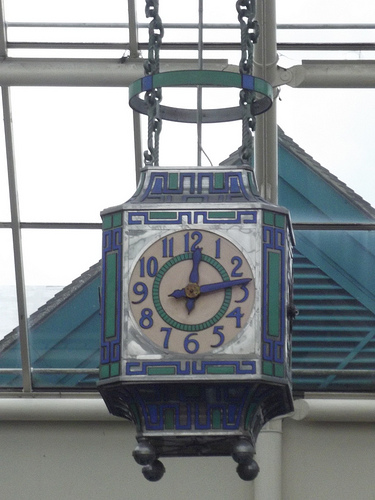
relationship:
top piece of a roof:
[217, 125, 317, 167] [1, 125, 374, 389]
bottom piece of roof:
[2, 373, 374, 394] [1, 125, 374, 389]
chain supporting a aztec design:
[236, 0, 262, 166] [95, 167, 296, 482]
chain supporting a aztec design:
[145, 1, 165, 165] [95, 167, 296, 482]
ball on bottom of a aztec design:
[229, 440, 256, 464] [95, 167, 296, 482]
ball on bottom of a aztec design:
[235, 460, 260, 482] [95, 167, 296, 482]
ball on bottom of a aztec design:
[140, 461, 166, 482] [95, 167, 296, 482]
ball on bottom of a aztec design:
[130, 443, 156, 468] [95, 167, 296, 482]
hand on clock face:
[169, 278, 252, 301] [122, 211, 262, 382]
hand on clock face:
[186, 245, 203, 316] [122, 211, 262, 382]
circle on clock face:
[154, 252, 233, 332] [122, 211, 262, 382]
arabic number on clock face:
[183, 232, 205, 255] [122, 211, 262, 382]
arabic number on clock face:
[160, 238, 175, 260] [122, 211, 262, 382]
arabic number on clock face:
[229, 256, 247, 279] [122, 211, 262, 382]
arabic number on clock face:
[129, 282, 150, 307] [122, 211, 262, 382]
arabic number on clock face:
[139, 307, 155, 330] [122, 211, 262, 382]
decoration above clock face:
[140, 171, 255, 204] [122, 211, 262, 382]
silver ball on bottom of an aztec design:
[229, 440, 256, 464] [95, 167, 296, 482]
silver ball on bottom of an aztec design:
[235, 460, 260, 482] [95, 167, 296, 482]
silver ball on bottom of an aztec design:
[130, 443, 156, 468] [95, 167, 296, 482]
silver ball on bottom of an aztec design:
[140, 461, 166, 482] [95, 167, 296, 482]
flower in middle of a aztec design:
[183, 282, 200, 300] [95, 167, 296, 482]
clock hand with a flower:
[186, 245, 203, 316] [183, 282, 200, 300]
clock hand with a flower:
[169, 278, 252, 301] [183, 282, 200, 300]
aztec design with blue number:
[95, 167, 296, 482] [183, 232, 205, 255]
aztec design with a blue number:
[95, 167, 296, 482] [212, 236, 224, 261]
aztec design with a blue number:
[95, 167, 296, 482] [229, 256, 247, 279]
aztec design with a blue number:
[95, 167, 296, 482] [225, 306, 247, 329]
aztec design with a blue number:
[95, 167, 296, 482] [139, 254, 160, 279]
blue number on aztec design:
[157, 326, 176, 351] [95, 167, 296, 482]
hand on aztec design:
[186, 245, 203, 316] [95, 167, 296, 482]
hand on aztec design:
[169, 278, 252, 301] [95, 167, 296, 482]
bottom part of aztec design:
[95, 375, 296, 483] [95, 167, 296, 482]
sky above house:
[3, 3, 374, 59] [1, 125, 374, 389]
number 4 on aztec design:
[225, 306, 247, 329] [95, 167, 296, 482]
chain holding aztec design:
[236, 0, 262, 166] [95, 167, 296, 482]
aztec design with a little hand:
[95, 167, 296, 482] [186, 245, 203, 316]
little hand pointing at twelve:
[186, 245, 203, 316] [183, 232, 205, 255]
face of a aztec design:
[122, 211, 262, 382] [95, 167, 296, 482]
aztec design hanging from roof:
[95, 167, 296, 482] [0, 0, 374, 398]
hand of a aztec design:
[186, 245, 203, 316] [95, 167, 296, 482]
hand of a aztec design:
[169, 278, 252, 301] [95, 167, 296, 482]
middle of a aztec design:
[122, 211, 262, 382] [95, 167, 296, 482]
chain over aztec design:
[145, 1, 165, 165] [95, 167, 296, 482]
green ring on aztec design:
[154, 252, 233, 332] [95, 167, 296, 482]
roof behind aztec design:
[0, 0, 374, 398] [95, 167, 296, 482]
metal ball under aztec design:
[130, 443, 156, 468] [95, 167, 296, 482]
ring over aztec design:
[128, 69, 275, 124] [95, 167, 296, 482]